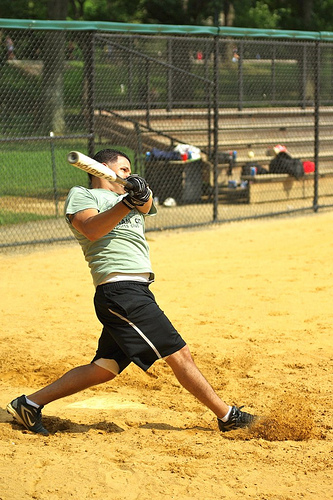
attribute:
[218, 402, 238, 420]
sock — white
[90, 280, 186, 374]
shorts — black, stripe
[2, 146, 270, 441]
person — playing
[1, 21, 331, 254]
link fence — black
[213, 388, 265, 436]
cleat — black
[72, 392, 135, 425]
home base — white, dirty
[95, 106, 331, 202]
stands — metal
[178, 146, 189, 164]
cup — red, plastic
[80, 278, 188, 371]
shorts — black and white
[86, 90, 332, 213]
bleacher — metal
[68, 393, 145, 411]
homeplate — dirty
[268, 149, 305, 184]
bag — black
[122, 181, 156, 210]
gloves — black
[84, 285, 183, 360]
shorts — black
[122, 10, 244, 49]
top — green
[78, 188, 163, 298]
shirt — green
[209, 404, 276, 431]
cleats — baseball